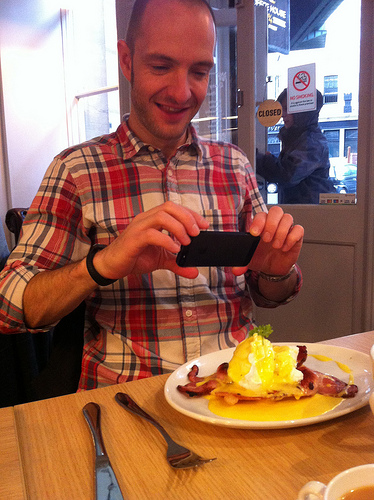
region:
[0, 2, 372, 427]
man taking a picture of his food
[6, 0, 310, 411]
man holding his phone with two hands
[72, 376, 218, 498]
eating utensils on the table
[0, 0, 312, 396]
man with a plaid shirt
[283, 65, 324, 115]
"no smoking" sign on the door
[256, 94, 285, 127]
"closed" sign on the door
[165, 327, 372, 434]
plate of bacon and eggs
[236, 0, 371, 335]
woman entering through the door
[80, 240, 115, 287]
black wrist band on the man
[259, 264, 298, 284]
metal watch on the wrist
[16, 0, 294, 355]
man taking picture of his food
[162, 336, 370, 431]
food on a plate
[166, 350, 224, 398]
strips of bacon on the plate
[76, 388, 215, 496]
knife and fork on the table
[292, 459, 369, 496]
cup of tea in the bottom right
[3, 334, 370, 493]
food on a wooden table top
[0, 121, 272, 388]
man wearing blue,red and white shirt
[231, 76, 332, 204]
woman about to enter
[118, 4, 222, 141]
man is smiling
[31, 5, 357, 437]
Man taking picture of his food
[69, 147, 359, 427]
Someone taking a picture of eggs and bacon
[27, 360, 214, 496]
Fork and spoon next to a plate of food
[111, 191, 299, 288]
Cellphone camera held by two hands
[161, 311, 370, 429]
Poached eggs and bacon slices plate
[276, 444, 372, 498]
Part of a cup of coffee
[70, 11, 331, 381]
Man smiling as he takes a picture of his food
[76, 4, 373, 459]
Man smiling while looking at his food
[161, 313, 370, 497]
Plate of food with coffee on table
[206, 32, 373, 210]
Woman in black jacket walking into doorway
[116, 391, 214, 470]
a fork on the table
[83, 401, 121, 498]
this is a knife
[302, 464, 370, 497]
a cup of coffee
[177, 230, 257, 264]
a black smartphone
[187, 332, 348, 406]
a delicious plate of bacon with eggs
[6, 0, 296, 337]
he is taking a photo with his smartphone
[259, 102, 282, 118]
it says closed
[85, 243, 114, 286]
a black men wristwatch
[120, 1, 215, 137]
the head of the man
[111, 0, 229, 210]
he is smiling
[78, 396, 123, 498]
Knife on the table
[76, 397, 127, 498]
Knife is on the table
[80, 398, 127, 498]
Butter knife on the table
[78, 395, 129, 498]
Butter knife is on the table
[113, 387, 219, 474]
Fork on the table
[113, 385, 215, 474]
Fork is on the table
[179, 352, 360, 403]
Bacon on a plate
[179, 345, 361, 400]
Bacon is on a plate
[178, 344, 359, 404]
Slices of bacon on a plate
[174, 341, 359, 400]
Slices of bacon are on a plate